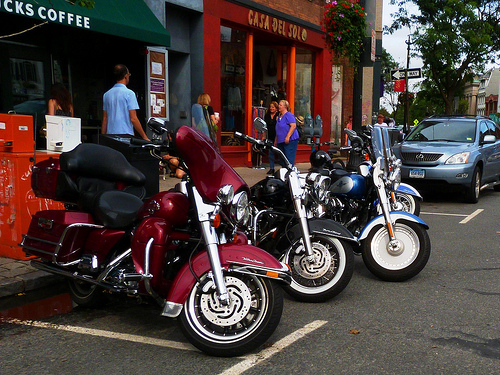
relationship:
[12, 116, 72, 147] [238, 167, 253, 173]
machines on sidewalk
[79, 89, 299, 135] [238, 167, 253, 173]
people on sidewalk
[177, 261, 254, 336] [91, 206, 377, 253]
wheel of motorcycles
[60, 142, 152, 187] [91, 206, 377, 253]
seat of motorcycles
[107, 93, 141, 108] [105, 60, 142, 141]
shirt on man